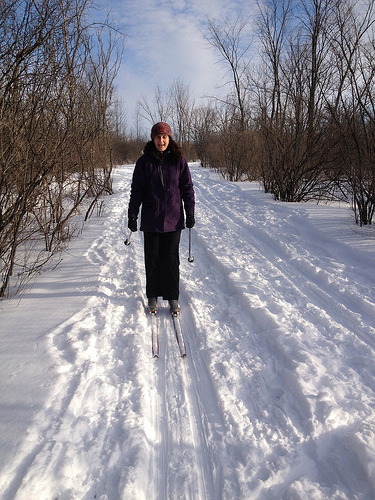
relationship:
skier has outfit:
[135, 115, 189, 173] [121, 140, 200, 300]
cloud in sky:
[0, 0, 375, 147] [124, 29, 202, 75]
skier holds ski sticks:
[128, 122, 195, 317] [117, 224, 198, 265]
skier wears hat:
[128, 122, 195, 317] [146, 118, 177, 135]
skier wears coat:
[128, 122, 195, 317] [108, 95, 225, 255]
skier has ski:
[128, 122, 195, 317] [147, 314, 159, 358]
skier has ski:
[128, 122, 195, 317] [170, 315, 188, 357]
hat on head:
[145, 116, 173, 139] [145, 117, 174, 152]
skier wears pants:
[128, 122, 195, 317] [142, 225, 182, 302]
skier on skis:
[128, 122, 195, 317] [125, 293, 223, 395]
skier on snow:
[128, 122, 195, 317] [64, 205, 278, 401]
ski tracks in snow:
[147, 309, 222, 498] [0, 162, 372, 498]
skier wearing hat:
[128, 122, 195, 317] [150, 121, 171, 138]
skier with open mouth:
[128, 122, 195, 317] [157, 142, 165, 149]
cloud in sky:
[64, 3, 297, 132] [1, 1, 370, 146]